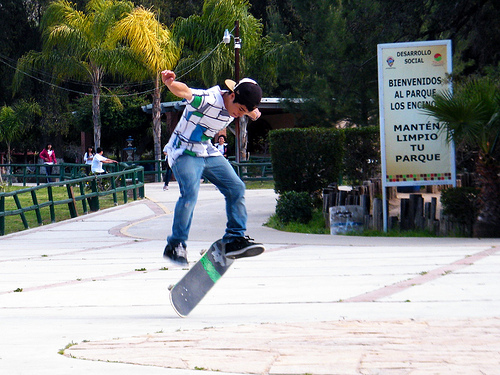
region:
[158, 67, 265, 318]
A young man performing a skateboard trick.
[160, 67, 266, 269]
A boy wearing a black baseball cap backwards.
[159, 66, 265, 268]
A boy wearing a white patterned shirt.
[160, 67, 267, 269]
A boy wearing blue jeans.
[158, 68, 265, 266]
A boy wearing black shoes.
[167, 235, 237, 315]
A black skateboard with a white skull design on it.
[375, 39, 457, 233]
A tall sign printed in spanish.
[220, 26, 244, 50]
A street light.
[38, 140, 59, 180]
A person in a red shirt.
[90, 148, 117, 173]
A person in a white shirt.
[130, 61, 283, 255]
this is a boy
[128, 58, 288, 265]
the boy is skating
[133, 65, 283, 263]
the boy is on air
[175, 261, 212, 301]
this is the skate board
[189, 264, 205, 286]
the board is black in color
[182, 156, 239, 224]
these are the legs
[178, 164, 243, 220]
the legs are apart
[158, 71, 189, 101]
this is the hand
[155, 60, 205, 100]
the hand is raised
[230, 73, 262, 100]
this is a snap back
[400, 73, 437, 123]
part of a board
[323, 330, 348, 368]
part of a floor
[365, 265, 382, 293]
part of a floor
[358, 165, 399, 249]
part of a stand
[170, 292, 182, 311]
edge of a board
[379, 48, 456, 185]
sign written in spanish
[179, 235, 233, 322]
skateboard in the air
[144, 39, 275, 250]
boy doing a trick with the skateboard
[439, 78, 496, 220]
palm tree by the sign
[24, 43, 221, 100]
power lines behind the boy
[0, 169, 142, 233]
green fence bordering the cement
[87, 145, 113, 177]
person near the fence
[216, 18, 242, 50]
light on the pole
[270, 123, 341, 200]
bushes behind the boy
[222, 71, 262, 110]
boy is wearing a hat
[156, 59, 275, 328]
boy jumps on skateboard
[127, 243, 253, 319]
black and green board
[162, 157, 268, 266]
boy has blue pants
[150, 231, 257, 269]
black and white shoes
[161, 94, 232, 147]
white blue and green shirt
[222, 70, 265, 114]
black and yellow cap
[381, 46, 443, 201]
white frame on sign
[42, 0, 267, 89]
green and yellow trees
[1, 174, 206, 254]
green fence behind boy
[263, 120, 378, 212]
green bushes behind boy